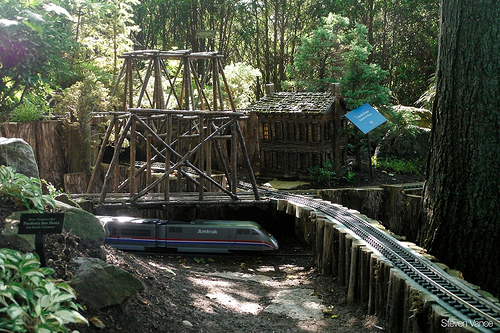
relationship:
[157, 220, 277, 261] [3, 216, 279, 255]
section of train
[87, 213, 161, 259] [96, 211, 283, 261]
section on train